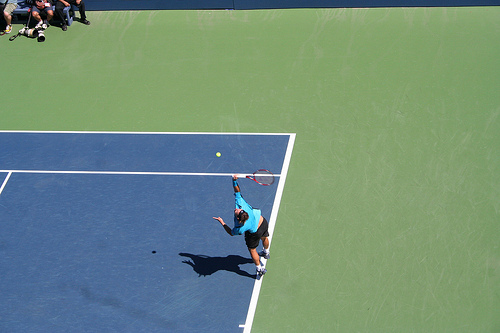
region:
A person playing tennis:
[195, 147, 290, 279]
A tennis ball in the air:
[212, 148, 230, 163]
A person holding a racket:
[229, 163, 283, 185]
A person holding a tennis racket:
[222, 168, 278, 190]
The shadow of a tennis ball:
[147, 244, 159, 259]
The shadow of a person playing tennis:
[173, 245, 264, 285]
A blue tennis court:
[7, 118, 278, 328]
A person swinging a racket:
[206, 155, 285, 281]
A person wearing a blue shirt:
[220, 187, 270, 239]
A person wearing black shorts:
[243, 225, 273, 247]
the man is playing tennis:
[87, 128, 339, 319]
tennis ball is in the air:
[140, 130, 291, 217]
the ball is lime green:
[185, 130, 237, 169]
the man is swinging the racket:
[187, 135, 304, 287]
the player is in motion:
[167, 135, 302, 285]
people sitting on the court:
[2, 0, 94, 65]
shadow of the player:
[120, 221, 289, 298]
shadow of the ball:
[115, 236, 167, 273]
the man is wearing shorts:
[239, 219, 276, 251]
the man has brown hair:
[220, 202, 260, 227]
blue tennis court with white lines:
[4, 122, 296, 328]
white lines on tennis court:
[4, 123, 303, 332]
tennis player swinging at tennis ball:
[200, 146, 276, 279]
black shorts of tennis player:
[241, 220, 273, 255]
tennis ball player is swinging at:
[209, 152, 226, 161]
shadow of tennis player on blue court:
[179, 245, 259, 287]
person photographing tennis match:
[20, 3, 57, 47]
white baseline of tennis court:
[225, 128, 301, 332]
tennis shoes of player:
[247, 251, 273, 276]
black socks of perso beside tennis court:
[57, 3, 93, 32]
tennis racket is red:
[216, 157, 286, 198]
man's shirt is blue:
[205, 181, 262, 231]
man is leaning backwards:
[210, 175, 295, 275]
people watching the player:
[0, 0, 95, 35]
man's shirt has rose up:
[237, 200, 277, 241]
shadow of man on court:
[160, 235, 251, 286]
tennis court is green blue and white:
[0, 5, 498, 329]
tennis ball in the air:
[202, 129, 239, 166]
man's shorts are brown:
[0, 0, 17, 17]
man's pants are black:
[78, 0, 88, 24]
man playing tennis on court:
[200, 178, 273, 276]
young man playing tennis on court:
[178, 162, 284, 275]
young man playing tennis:
[201, 168, 298, 301]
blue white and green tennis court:
[0, 115, 54, 190]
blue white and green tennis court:
[64, 122, 130, 194]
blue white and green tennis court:
[132, 97, 193, 200]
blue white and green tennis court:
[206, 117, 316, 150]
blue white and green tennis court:
[3, 159, 79, 214]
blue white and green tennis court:
[102, 160, 165, 205]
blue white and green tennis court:
[22, 230, 113, 283]